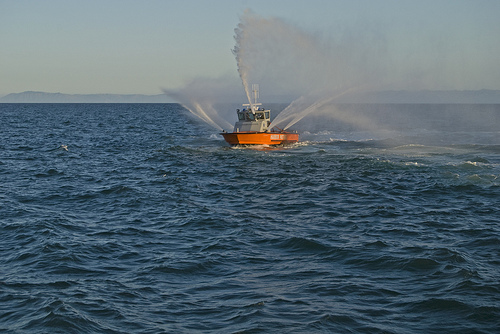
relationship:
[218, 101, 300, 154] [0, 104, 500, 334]
boat floating on ocean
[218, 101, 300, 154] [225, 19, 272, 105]
boat spraying water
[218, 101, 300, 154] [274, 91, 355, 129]
boat spraying water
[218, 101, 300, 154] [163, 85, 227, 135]
boat spraying water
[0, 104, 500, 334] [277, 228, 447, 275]
ocean has waves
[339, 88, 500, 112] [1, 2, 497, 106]
mountains are in background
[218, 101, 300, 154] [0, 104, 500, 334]
boat in ocean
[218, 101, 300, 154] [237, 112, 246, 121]
boat has window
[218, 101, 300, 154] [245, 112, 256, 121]
boat has window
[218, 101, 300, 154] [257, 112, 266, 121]
boat has window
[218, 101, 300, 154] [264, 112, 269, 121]
boat has window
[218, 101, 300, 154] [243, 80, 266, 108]
boat has antenna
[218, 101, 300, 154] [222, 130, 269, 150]
boat has hull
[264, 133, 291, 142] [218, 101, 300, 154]
words are on side of boat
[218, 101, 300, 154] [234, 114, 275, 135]
boat has cabin